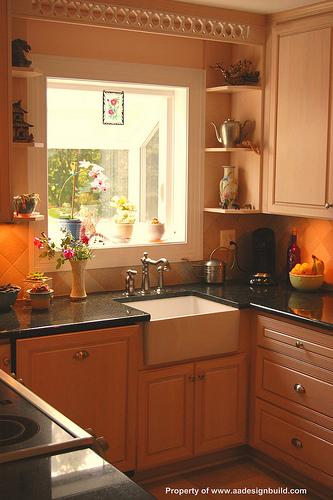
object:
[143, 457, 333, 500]
floor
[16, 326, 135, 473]
cabinets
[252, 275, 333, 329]
countertop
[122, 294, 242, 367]
sink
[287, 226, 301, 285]
bottle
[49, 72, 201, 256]
window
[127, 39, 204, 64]
wall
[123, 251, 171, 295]
faucet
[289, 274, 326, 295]
bowl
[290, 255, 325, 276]
fruit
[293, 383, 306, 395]
knobs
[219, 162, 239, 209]
vase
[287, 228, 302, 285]
wine bottle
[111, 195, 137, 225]
plant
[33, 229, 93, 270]
flowers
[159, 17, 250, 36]
trim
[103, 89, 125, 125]
decoration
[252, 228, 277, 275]
coffee maker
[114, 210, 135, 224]
cactus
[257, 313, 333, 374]
drawers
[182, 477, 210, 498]
tile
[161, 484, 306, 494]
watermark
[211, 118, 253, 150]
teapot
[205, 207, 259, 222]
shelf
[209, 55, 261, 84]
figurine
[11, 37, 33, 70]
figurine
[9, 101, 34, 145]
figurine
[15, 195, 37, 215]
plant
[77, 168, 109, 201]
orchid